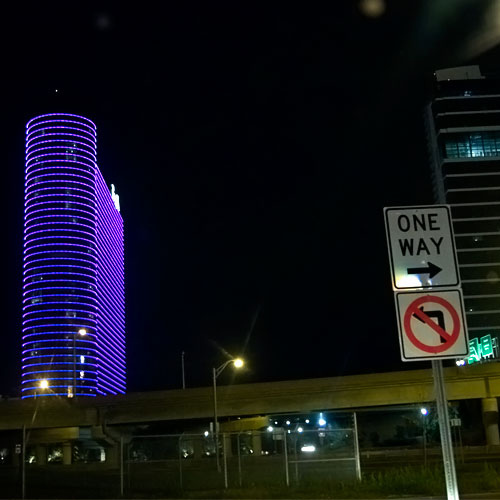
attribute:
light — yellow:
[204, 351, 256, 381]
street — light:
[12, 477, 497, 498]